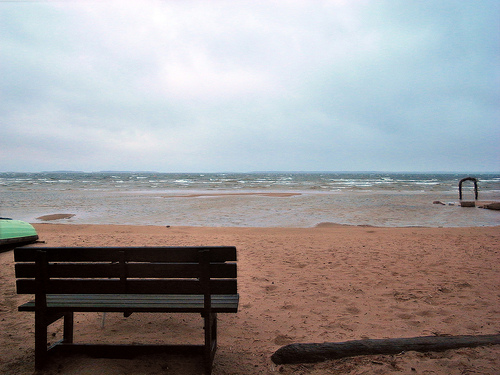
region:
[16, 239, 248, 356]
a bench on a beach.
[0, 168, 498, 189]
a clear green blue ocean.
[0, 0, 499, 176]
a cloud filled sky.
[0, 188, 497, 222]
a waved soaked beach.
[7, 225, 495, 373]
a dry sandy beach.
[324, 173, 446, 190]
a large foamy wave.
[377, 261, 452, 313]
foot prints in sand.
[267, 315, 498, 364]
a piece of wood on sand.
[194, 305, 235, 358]
a leg on a bench.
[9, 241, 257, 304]
the back of a bench.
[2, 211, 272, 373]
this is a bench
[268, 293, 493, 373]
this is a log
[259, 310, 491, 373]
the log is brown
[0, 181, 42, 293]
this is a turned over boat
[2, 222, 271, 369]
the bench is brown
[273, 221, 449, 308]
this is tan sand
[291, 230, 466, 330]
multiple footsteps in sand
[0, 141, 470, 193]
blue water in the distance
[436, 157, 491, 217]
this is a rock structure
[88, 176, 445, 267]
the water is on the beach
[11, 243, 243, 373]
a small brown bench on a beach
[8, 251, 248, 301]
the back part of a bench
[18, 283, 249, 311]
the seat of a bench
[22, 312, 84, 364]
the left leg side of a bench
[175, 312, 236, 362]
the right leg side of a bench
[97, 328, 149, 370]
the shadow of a park bench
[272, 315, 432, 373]
a dead log on the beach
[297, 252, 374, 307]
a bunch of sand on the beach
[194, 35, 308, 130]
the sunlight beaming through the clouds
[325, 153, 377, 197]
waves crashing in the ocean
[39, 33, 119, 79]
white clouds in blue sky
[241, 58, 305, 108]
white clouds in blue sky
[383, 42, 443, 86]
white clouds in blue sky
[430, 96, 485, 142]
white clouds in blue sky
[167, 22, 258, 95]
white clouds in blue sky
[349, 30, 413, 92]
white clouds in blue sky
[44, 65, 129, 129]
white clouds in blue sky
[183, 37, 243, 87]
white clouds in blue sky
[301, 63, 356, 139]
white clouds in blue sky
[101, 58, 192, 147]
white clouds in blue sky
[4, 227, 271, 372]
a brown wooden bench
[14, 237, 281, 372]
a brown wooden bench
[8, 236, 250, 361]
a brown wooden bench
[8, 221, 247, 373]
a brown wooden bench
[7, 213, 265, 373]
the bench is empty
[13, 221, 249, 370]
the bench is empty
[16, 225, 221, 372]
the bench is empty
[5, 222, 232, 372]
the bench is empty